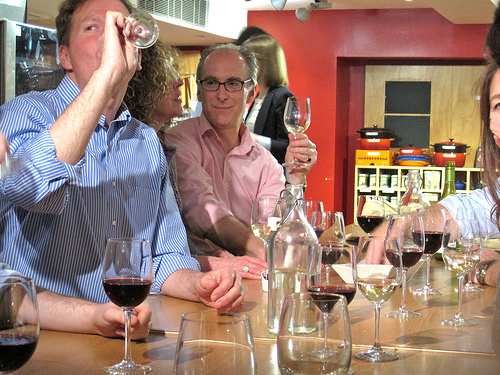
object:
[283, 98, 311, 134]
shine reflection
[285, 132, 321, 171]
finger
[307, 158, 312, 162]
ring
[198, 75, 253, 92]
black rim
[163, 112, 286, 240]
shirt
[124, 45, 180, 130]
curly hair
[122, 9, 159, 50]
glass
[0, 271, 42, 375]
glass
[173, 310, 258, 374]
glass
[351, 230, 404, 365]
glass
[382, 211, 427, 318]
glass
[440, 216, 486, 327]
glass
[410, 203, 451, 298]
glass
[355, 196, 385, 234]
glass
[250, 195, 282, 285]
glass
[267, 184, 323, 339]
glass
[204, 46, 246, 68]
bald head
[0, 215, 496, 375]
table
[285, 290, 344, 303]
glass edge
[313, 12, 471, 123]
wall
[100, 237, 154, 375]
cup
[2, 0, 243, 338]
man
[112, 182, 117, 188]
button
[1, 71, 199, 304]
shirt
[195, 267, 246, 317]
man's hand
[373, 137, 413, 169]
ground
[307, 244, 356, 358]
glass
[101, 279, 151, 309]
wine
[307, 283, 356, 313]
wine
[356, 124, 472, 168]
cooking utensils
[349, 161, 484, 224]
shelf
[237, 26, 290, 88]
woman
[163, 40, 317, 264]
man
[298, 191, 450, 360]
wine glasses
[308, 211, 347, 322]
glass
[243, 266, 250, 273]
ring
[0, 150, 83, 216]
elbow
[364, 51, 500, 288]
woman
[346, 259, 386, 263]
food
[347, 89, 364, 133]
edge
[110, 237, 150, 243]
edge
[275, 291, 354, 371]
glass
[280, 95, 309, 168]
glass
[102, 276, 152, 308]
red wine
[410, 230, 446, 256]
red wine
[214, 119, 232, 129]
chin